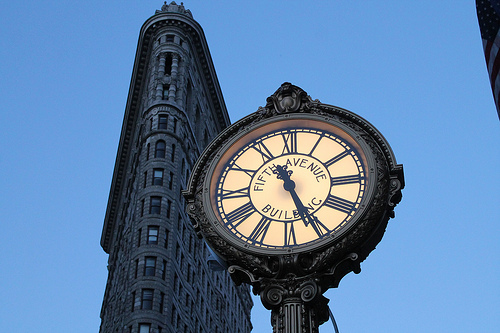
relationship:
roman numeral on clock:
[281, 217, 298, 249] [216, 127, 366, 247]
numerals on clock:
[224, 199, 259, 228] [216, 127, 366, 247]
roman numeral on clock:
[280, 130, 300, 155] [216, 127, 366, 247]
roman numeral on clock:
[249, 140, 275, 162] [216, 127, 366, 247]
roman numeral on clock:
[215, 188, 249, 199] [216, 127, 366, 247]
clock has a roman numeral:
[216, 127, 366, 247] [281, 217, 298, 249]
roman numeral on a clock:
[319, 190, 362, 215] [216, 127, 366, 247]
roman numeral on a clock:
[327, 170, 359, 187] [216, 127, 366, 247]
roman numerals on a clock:
[308, 130, 326, 156] [216, 127, 366, 247]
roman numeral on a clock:
[247, 140, 272, 160] [216, 127, 366, 247]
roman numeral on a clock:
[215, 183, 249, 203] [216, 127, 366, 247]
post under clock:
[269, 301, 318, 331] [207, 113, 373, 249]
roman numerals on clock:
[220, 126, 368, 246] [216, 127, 366, 247]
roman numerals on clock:
[220, 126, 368, 246] [220, 107, 392, 259]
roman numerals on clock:
[220, 126, 368, 246] [281, 209, 331, 247]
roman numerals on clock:
[308, 130, 326, 156] [216, 127, 366, 247]